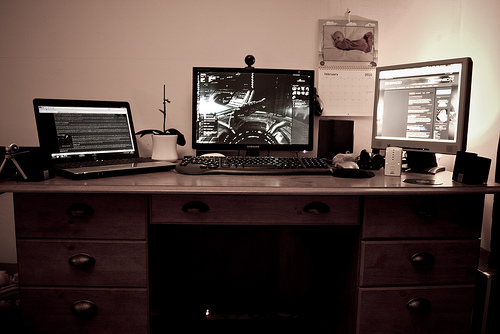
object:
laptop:
[32, 98, 176, 181]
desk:
[0, 159, 498, 333]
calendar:
[317, 18, 379, 117]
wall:
[1, 1, 500, 264]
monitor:
[192, 67, 315, 157]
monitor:
[371, 57, 473, 175]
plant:
[134, 84, 187, 146]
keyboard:
[175, 156, 333, 175]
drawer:
[13, 192, 148, 240]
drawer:
[16, 239, 149, 287]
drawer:
[149, 195, 360, 225]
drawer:
[362, 194, 485, 238]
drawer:
[358, 240, 481, 286]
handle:
[66, 203, 94, 219]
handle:
[68, 253, 96, 270]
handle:
[182, 201, 210, 214]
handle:
[418, 207, 436, 218]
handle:
[410, 252, 435, 268]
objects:
[1, 55, 492, 186]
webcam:
[245, 55, 255, 66]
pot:
[151, 134, 178, 162]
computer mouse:
[335, 160, 359, 169]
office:
[1, 0, 500, 333]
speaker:
[17, 152, 56, 182]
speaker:
[452, 152, 492, 185]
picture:
[323, 25, 376, 62]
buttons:
[237, 164, 244, 170]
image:
[197, 72, 310, 144]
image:
[377, 72, 459, 141]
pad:
[332, 169, 375, 178]